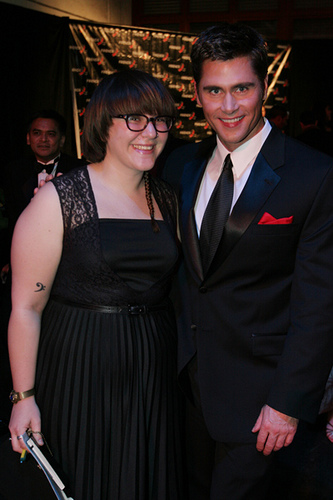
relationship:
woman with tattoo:
[32, 168, 180, 500] [34, 281, 45, 295]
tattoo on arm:
[34, 281, 45, 295] [8, 182, 66, 390]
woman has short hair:
[2, 63, 182, 499] [84, 69, 178, 167]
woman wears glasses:
[2, 63, 182, 499] [109, 111, 174, 131]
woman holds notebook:
[2, 63, 182, 499] [20, 432, 75, 499]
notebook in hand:
[20, 432, 75, 499] [8, 395, 44, 454]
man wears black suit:
[164, 24, 331, 499] [165, 126, 332, 499]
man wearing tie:
[164, 24, 331, 499] [194, 154, 234, 279]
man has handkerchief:
[164, 24, 331, 499] [258, 214, 295, 228]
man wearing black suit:
[164, 24, 331, 499] [165, 126, 332, 499]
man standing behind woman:
[164, 24, 331, 499] [2, 63, 182, 499]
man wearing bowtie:
[4, 107, 91, 246] [35, 160, 56, 175]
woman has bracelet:
[2, 63, 182, 499] [9, 385, 36, 408]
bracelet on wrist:
[9, 385, 36, 408] [9, 382, 39, 409]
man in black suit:
[164, 24, 331, 499] [165, 126, 332, 499]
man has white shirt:
[164, 24, 331, 499] [190, 119, 272, 238]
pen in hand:
[20, 448, 28, 466] [8, 395, 44, 454]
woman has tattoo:
[2, 63, 182, 499] [34, 281, 45, 295]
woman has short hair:
[2, 63, 182, 499] [80, 69, 178, 167]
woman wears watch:
[2, 63, 182, 499] [9, 385, 36, 408]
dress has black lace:
[32, 168, 180, 500] [48, 164, 102, 228]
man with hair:
[164, 24, 331, 499] [187, 24, 269, 91]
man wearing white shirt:
[164, 24, 331, 499] [190, 119, 272, 238]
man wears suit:
[164, 24, 331, 499] [165, 126, 332, 499]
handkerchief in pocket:
[258, 214, 295, 228] [260, 225, 298, 247]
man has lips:
[164, 24, 331, 499] [218, 114, 247, 128]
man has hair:
[164, 24, 331, 499] [187, 24, 269, 91]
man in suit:
[164, 24, 331, 499] [165, 126, 332, 499]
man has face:
[164, 24, 331, 499] [192, 48, 270, 144]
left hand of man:
[248, 402, 298, 455] [164, 24, 331, 499]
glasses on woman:
[109, 111, 174, 131] [2, 63, 182, 499]